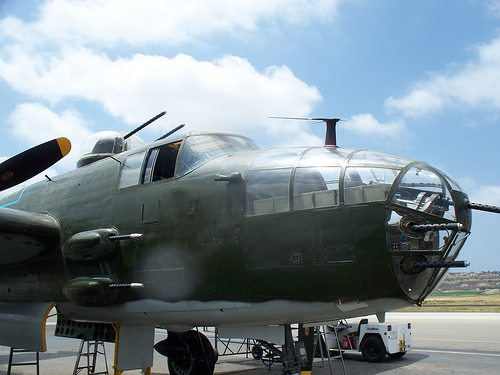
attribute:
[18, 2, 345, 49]
clouds — are moderate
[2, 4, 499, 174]
sky — is blue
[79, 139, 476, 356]
vehicle — white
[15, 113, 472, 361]
plane — part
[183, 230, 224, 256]
metal — part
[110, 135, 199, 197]
window — is vintage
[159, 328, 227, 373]
wheel — is black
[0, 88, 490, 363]
airplane — is grey, is old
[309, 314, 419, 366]
vehicle — is small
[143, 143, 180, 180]
window — open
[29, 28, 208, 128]
clouds — are large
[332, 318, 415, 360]
vehicle — white 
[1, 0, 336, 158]
cloud — is white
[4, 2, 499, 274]
sky — is blue, is cloudy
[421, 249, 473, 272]
metal — part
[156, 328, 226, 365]
wheel — is rubber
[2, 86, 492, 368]
scene — is military 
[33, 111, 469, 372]
bomber — is vintage, nose, cockpit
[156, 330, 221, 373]
wheel — large 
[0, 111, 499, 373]
plane — part, gray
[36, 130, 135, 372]
accents — yellow 